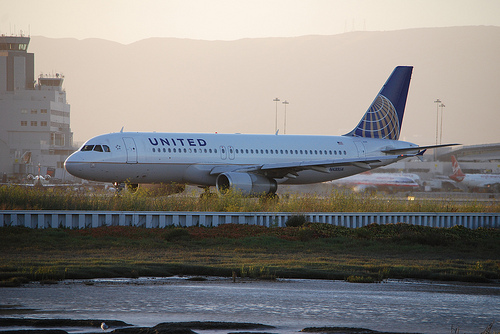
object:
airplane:
[63, 66, 462, 198]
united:
[148, 137, 206, 146]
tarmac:
[438, 193, 463, 198]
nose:
[61, 158, 81, 170]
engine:
[216, 171, 278, 197]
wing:
[249, 157, 381, 178]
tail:
[340, 65, 415, 140]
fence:
[0, 209, 500, 229]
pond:
[0, 275, 500, 333]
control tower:
[0, 24, 82, 183]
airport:
[0, 24, 500, 211]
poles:
[274, 101, 278, 134]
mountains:
[23, 25, 500, 153]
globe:
[353, 95, 399, 141]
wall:
[0, 210, 500, 230]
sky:
[0, 0, 500, 44]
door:
[120, 136, 138, 163]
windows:
[101, 145, 109, 154]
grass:
[0, 184, 500, 212]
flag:
[397, 175, 412, 182]